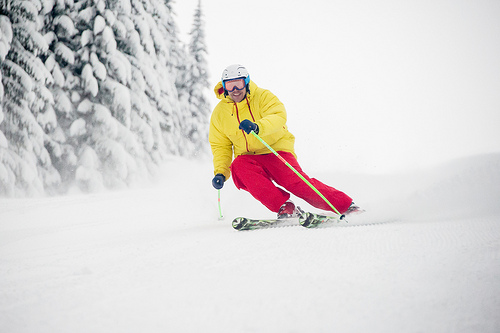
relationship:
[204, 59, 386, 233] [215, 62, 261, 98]
man has helmet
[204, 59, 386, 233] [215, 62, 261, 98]
man in helmet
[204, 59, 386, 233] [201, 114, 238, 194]
man has right arm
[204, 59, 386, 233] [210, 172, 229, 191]
man has right hand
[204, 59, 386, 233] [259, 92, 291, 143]
man has left arm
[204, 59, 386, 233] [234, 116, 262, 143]
man has left hand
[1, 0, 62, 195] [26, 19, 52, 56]
tree has snow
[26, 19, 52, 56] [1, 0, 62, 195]
snow on tree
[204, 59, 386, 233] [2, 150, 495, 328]
man coming down mountain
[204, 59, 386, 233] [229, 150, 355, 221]
man has pants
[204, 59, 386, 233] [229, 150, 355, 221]
man wearing pants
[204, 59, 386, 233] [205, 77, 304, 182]
man wearing sweatshirt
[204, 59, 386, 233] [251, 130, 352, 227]
man holding ski pole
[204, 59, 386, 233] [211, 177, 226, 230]
man holding ski pole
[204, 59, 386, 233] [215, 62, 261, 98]
man wearing helmet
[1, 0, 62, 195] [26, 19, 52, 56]
tree covered in snow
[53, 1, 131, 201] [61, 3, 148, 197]
tree covered in snow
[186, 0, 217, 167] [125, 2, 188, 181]
tree covered in snow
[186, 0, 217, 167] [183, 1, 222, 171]
tree covered in snow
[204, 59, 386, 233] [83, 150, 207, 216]
man kicking up snow dust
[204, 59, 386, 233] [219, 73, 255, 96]
man wearing ski goggles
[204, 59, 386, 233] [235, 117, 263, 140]
man wearing glove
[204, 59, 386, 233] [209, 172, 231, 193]
man wearing glove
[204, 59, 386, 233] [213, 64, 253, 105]
man has head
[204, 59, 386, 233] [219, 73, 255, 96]
man has ski goggles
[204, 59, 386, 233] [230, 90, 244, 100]
man has mouth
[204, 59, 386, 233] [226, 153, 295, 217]
man has leg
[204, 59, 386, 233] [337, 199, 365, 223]
man has foot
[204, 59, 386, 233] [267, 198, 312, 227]
man has foot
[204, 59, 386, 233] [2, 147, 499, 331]
man in snow